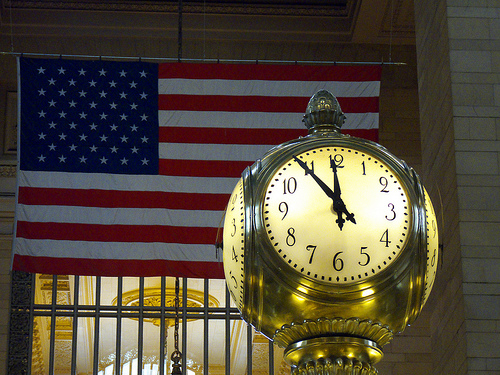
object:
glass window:
[34, 274, 271, 374]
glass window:
[57, 276, 73, 305]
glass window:
[77, 276, 96, 306]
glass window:
[98, 276, 120, 305]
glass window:
[143, 276, 160, 308]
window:
[202, 279, 229, 308]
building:
[0, 1, 499, 374]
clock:
[261, 142, 413, 287]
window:
[36, 270, 64, 308]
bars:
[201, 281, 210, 375]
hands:
[328, 158, 343, 233]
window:
[72, 315, 94, 374]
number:
[280, 177, 298, 198]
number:
[277, 201, 292, 222]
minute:
[292, 156, 359, 226]